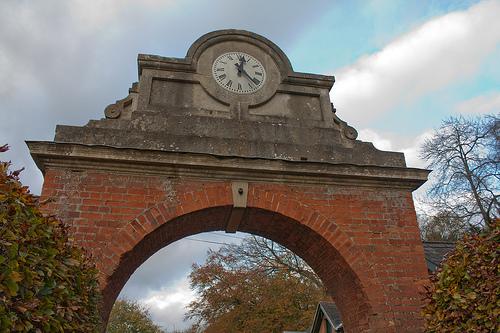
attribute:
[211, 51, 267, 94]
clock — white, large, black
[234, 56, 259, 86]
hands — black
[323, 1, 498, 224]
clouds — white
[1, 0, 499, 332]
sky — blue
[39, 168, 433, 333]
arch — red, brick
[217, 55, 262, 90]
numerals — roman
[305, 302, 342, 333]
roof — pointed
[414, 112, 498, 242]
tree — on right, in distance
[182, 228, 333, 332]
tree — in middle, in distance, leafy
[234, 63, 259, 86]
hand — minute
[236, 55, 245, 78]
hand — hour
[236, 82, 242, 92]
numeral — vi, roman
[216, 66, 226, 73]
numeral — 9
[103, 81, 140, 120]
scrollwork — cement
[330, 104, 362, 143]
scrollwork — cement